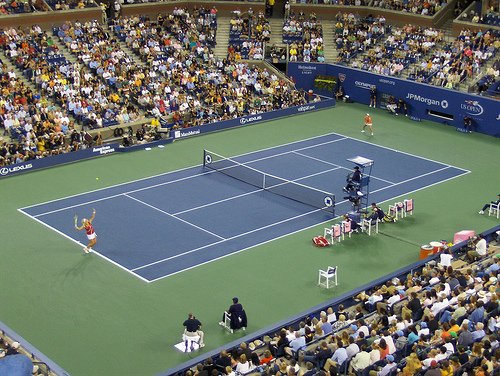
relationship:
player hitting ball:
[73, 212, 102, 257] [93, 177, 99, 183]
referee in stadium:
[347, 158, 372, 209] [1, 1, 500, 373]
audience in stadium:
[0, 2, 499, 176] [1, 1, 500, 373]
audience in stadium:
[159, 223, 497, 375] [1, 1, 500, 373]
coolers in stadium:
[421, 229, 478, 264] [1, 1, 500, 373]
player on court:
[363, 113, 375, 140] [18, 130, 472, 286]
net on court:
[200, 149, 341, 215] [18, 130, 472, 286]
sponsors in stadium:
[285, 56, 498, 139] [1, 1, 500, 373]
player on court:
[73, 212, 102, 257] [18, 130, 472, 286]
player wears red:
[73, 212, 102, 257] [83, 223, 96, 236]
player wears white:
[73, 212, 102, 257] [87, 236, 97, 242]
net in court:
[200, 149, 341, 215] [18, 130, 472, 286]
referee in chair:
[347, 158, 372, 209] [350, 156, 373, 208]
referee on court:
[347, 158, 372, 209] [18, 130, 472, 286]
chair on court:
[319, 265, 340, 290] [18, 130, 472, 286]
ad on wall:
[404, 89, 452, 114] [291, 60, 499, 141]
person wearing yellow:
[403, 351, 421, 372] [405, 352, 418, 375]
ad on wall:
[3, 161, 32, 178] [0, 85, 335, 186]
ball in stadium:
[93, 177, 99, 183] [1, 1, 500, 373]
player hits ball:
[73, 212, 102, 257] [93, 177, 99, 183]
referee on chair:
[347, 158, 372, 209] [350, 156, 373, 208]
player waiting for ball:
[363, 113, 375, 140] [93, 177, 99, 183]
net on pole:
[200, 149, 341, 215] [202, 151, 210, 170]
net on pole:
[200, 149, 341, 215] [331, 185, 336, 220]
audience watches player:
[0, 2, 499, 176] [73, 212, 102, 257]